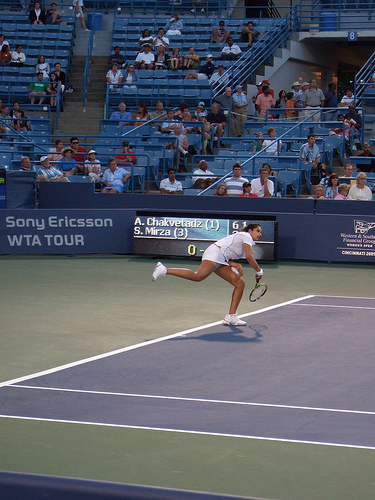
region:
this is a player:
[137, 216, 284, 351]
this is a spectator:
[225, 159, 247, 198]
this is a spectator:
[246, 163, 277, 195]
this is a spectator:
[348, 161, 372, 206]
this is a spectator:
[150, 165, 201, 195]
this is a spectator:
[92, 148, 141, 204]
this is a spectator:
[157, 166, 181, 202]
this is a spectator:
[180, 148, 221, 194]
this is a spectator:
[102, 91, 135, 125]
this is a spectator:
[262, 114, 284, 160]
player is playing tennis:
[122, 201, 283, 348]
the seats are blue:
[172, 107, 283, 199]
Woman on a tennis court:
[149, 224, 273, 337]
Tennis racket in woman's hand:
[244, 272, 270, 304]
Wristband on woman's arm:
[250, 261, 266, 281]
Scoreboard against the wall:
[132, 212, 285, 268]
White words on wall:
[4, 215, 119, 249]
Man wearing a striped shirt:
[222, 160, 249, 196]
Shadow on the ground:
[155, 318, 272, 352]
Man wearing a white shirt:
[154, 168, 185, 197]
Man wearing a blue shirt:
[299, 133, 320, 171]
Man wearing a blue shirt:
[105, 97, 133, 125]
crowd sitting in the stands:
[63, 18, 278, 189]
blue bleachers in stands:
[144, 73, 184, 93]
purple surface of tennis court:
[162, 347, 306, 410]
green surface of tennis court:
[135, 441, 206, 469]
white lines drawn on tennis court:
[86, 383, 197, 440]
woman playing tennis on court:
[135, 220, 276, 328]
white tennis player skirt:
[198, 246, 229, 265]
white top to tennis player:
[221, 233, 251, 261]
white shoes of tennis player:
[152, 262, 166, 274]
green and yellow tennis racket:
[242, 277, 269, 302]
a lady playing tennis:
[151, 222, 265, 327]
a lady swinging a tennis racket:
[150, 222, 264, 325]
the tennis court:
[2, 317, 374, 498]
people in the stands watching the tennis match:
[1, 1, 374, 201]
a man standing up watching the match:
[306, 78, 323, 121]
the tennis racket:
[250, 274, 266, 301]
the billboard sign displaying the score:
[133, 214, 206, 257]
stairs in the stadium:
[64, 0, 113, 145]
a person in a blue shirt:
[58, 146, 77, 176]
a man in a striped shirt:
[223, 163, 247, 191]